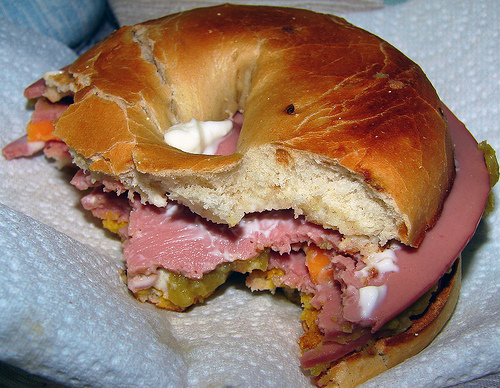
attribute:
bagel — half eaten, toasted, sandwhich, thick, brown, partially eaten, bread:
[3, 0, 499, 388]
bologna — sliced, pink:
[3, 63, 492, 370]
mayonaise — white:
[165, 116, 235, 157]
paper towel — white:
[1, 2, 500, 387]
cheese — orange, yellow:
[25, 121, 63, 147]